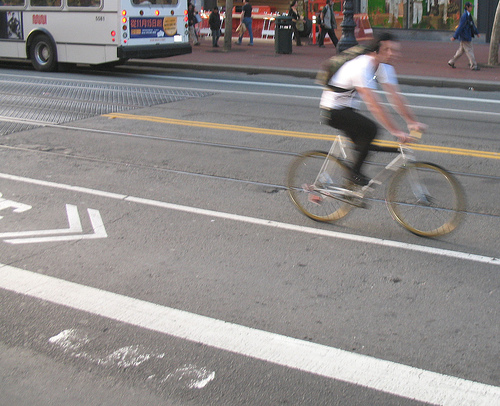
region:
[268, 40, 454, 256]
Guy riding a bicycle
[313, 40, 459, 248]
Man riding a bicycle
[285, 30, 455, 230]
Man with backpack riding a bicycle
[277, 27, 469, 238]
Guy with backpack riding a bicycle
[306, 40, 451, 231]
Guy wearing black and white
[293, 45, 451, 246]
Man wearing black and white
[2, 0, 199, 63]
Back of city bus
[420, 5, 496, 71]
Person walking down the street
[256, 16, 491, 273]
Man riding down the street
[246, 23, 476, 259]
Male riding down the street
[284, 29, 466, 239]
man in white top riding bike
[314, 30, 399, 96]
backpack on man riding bicycle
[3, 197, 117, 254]
white arrows painted on street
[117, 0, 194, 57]
back of a white city bus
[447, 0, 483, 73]
person in tan pants walking to the right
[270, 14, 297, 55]
trash can on the sidewalk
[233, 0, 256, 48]
man in blue jeans carrying jacket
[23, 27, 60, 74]
a back tire on white city bus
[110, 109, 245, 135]
double yellow line on street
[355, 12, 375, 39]
orange and white construction sign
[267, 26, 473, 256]
man riding a bicycle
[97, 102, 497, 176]
yellow stripe down center of road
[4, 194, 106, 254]
white painted arrows on road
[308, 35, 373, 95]
camoflauge backpack on man's back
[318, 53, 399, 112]
white short sleeve shirt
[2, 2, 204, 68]
bus stopped at bus stop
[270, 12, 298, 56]
black trash can on sidewalk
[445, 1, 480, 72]
man in blue jacket walking down sidewalk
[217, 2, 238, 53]
brown tree trunk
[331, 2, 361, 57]
base of tall street lamp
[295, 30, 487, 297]
a man riding a bicycle fast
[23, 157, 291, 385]
a bike lane on a paved road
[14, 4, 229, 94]
a stopped bus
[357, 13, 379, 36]
a traffic sign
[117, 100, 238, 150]
a double yellow line in the road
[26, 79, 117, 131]
a metal grate in the road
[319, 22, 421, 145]
a man wearing a camouflage backpack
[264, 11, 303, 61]
a public trash can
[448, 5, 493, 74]
a man in a blue jacket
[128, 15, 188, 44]
an ad on a bus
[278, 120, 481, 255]
a blurry white bike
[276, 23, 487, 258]
a man riding a bike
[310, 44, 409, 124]
a plain white tee shirt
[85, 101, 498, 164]
a yellow road line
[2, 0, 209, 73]
a white city bus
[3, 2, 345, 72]
people loading onto a bus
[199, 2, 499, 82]
people walking a city street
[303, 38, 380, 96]
a blurry travel sack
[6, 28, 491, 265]
a man rides a bike down the street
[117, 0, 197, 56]
an advertisement on a bus